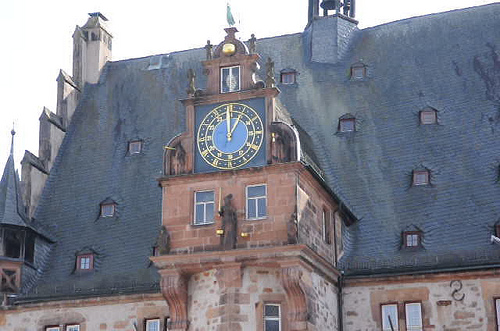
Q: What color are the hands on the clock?
A: Gold.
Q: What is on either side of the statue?
A: A window.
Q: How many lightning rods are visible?
A: One.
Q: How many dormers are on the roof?
A: Nine.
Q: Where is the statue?
A: Below the clock.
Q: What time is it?
A: 1:00.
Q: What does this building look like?
A: A church.